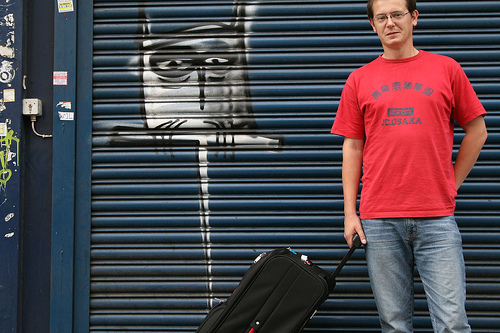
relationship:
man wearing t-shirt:
[333, 7, 491, 333] [330, 51, 486, 221]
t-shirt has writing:
[330, 51, 486, 221] [370, 81, 434, 127]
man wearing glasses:
[333, 7, 491, 333] [375, 13, 406, 19]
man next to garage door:
[333, 7, 491, 333] [92, 4, 497, 331]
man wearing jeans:
[333, 7, 491, 333] [357, 219, 469, 332]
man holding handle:
[333, 7, 491, 333] [331, 233, 366, 280]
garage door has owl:
[92, 4, 497, 331] [138, 1, 255, 134]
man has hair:
[333, 7, 491, 333] [366, 1, 415, 15]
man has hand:
[333, 7, 491, 333] [438, 169, 458, 194]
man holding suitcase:
[333, 7, 491, 333] [200, 247, 333, 332]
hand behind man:
[438, 169, 458, 194] [333, 7, 491, 333]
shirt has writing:
[330, 51, 486, 221] [370, 81, 434, 127]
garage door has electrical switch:
[92, 4, 497, 331] [22, 98, 43, 114]